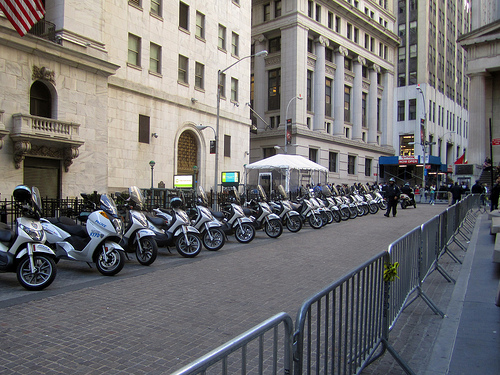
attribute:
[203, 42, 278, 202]
light — street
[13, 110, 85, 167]
balcony — stone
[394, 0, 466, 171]
building — stone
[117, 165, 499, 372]
barriers — metal, fence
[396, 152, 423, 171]
sign — red, white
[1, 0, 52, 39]
flag — American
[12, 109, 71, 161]
balcony — small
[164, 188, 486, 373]
fence — Silver , rail 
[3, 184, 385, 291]
mopeds — black, silver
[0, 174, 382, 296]
motorcycles — parked in line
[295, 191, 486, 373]
barrier — metal, temporary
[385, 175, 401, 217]
man — walking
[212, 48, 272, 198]
pole — metal, light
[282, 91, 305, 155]
pole — metal, light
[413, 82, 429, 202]
pole — metal, light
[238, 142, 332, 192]
tent — white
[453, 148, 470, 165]
flag — red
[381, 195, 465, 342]
fence — black , metal 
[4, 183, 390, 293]
row — motorbikes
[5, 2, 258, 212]
building — stone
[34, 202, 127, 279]
motorcycle — police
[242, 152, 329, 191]
canopy tent — white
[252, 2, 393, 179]
building — stone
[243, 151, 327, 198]
tent — white